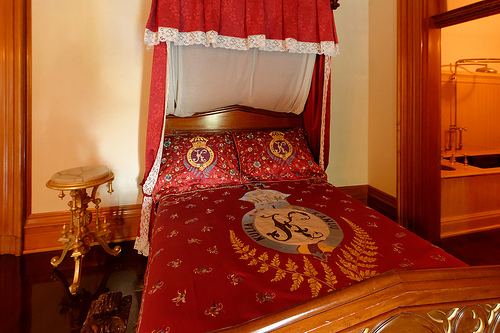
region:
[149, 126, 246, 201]
a pillow on a bed.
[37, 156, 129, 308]
a table near a bed.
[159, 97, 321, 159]
a wooden head board.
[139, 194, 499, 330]
a bed in a bedroom.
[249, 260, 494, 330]
a wooden footboard.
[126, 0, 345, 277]
a curtain over a window.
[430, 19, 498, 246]
a large doorway.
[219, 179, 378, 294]
a picture on a blanket.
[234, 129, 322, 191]
a red pillow with a picture on it.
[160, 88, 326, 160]
a shiny head board.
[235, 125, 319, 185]
pillow on a bed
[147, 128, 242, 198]
pillow on a bed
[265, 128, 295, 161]
gold design on a pillow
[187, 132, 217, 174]
gold design on a pillow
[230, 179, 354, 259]
gold design on a bed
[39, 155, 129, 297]
nightstand painted gold near a bed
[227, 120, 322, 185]
red pillow with design of gold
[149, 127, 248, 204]
red pillow with design of gold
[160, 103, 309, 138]
wooden headboard on bed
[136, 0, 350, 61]
red and white curtain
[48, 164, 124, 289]
ornate gold bedside table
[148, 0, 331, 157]
red and white fabric hanging above the bed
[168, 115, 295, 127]
wooden headboard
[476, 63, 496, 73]
metal shower head in the bathroom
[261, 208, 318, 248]
monogrammed bedspread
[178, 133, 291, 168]
pillowcases monogrammed with the letter K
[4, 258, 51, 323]
dark shiny floor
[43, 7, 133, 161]
beige wall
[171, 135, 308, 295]
matching bedspread and pillowcases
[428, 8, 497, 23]
wooden beam in the doorway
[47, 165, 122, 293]
ornate marble and gilt bedside table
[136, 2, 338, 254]
red and white bed curtains at the head of the bed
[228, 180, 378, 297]
a family crest in the center of the bedspread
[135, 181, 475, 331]
red bedspread with family crest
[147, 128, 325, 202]
red pillowcases with print and matching family crest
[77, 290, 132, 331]
strange looking object that may be a bed warmer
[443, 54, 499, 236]
bathroom fixtures in the next room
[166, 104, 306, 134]
polished wood headboard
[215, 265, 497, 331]
polished and carved wood footboard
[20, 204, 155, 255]
wood baseboards along the floor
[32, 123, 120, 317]
Gold colored stool with marble top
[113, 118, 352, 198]
Two red pillows with gold crowns and circle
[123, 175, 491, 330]
Red comforter with gold wreath and K logo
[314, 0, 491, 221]
Bathroom entrance from bedroom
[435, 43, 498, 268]
White bathtub and shower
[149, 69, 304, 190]
Brown headboard and two pillows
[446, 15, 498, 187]
Silver shower head in shower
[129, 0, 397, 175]
Red curtains on top of the bed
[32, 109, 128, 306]
Three legged gold colored table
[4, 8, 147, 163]
White wall with wooden trim